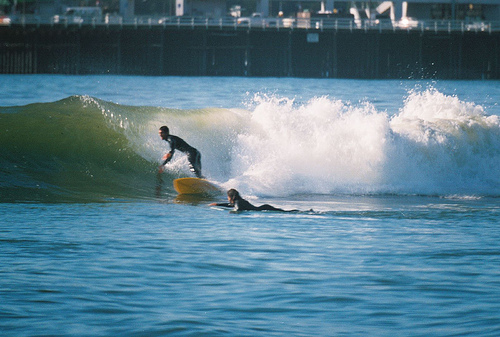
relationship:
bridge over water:
[153, 10, 449, 43] [165, 75, 430, 117]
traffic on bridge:
[158, 6, 280, 26] [0, 6, 437, 33]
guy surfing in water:
[158, 125, 206, 179] [19, 89, 474, 289]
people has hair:
[209, 188, 316, 214] [224, 183, 241, 206]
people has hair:
[209, 188, 316, 214] [156, 122, 175, 132]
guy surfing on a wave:
[152, 122, 205, 180] [0, 60, 499, 203]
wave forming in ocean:
[12, 88, 499, 224] [19, 211, 491, 333]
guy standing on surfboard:
[158, 125, 206, 179] [173, 171, 213, 195]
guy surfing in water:
[158, 125, 206, 179] [1, 75, 496, 333]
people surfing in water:
[219, 183, 316, 219] [1, 75, 496, 333]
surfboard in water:
[173, 176, 223, 194] [1, 75, 496, 333]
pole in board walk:
[161, 158, 274, 223] [1, 19, 498, 78]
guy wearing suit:
[158, 125, 206, 179] [170, 132, 215, 179]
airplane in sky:
[350, 7, 429, 32] [10, 1, 497, 50]